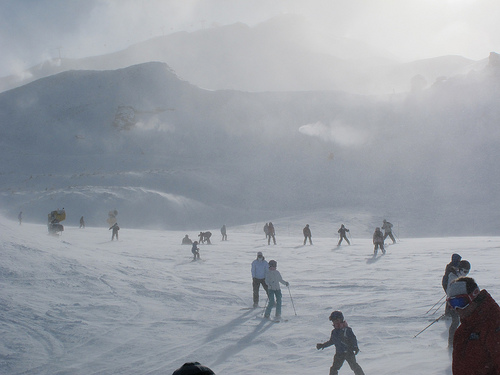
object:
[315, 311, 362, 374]
child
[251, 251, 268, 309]
person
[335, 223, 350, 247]
person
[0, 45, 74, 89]
hill side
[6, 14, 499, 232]
mountains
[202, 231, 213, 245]
person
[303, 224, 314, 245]
person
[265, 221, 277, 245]
person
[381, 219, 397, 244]
person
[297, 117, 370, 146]
snow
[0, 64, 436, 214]
hill side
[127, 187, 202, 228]
hill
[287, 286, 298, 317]
ski pole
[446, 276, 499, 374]
man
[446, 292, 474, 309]
goggles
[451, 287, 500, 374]
black coat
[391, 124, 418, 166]
ground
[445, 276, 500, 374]
people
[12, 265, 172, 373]
path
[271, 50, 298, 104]
snow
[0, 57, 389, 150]
hill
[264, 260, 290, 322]
people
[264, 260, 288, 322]
person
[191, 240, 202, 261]
children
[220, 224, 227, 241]
person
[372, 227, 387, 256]
people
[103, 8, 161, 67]
snow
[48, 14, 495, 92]
hill side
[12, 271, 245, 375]
tracks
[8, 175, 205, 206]
snow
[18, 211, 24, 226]
person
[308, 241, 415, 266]
snow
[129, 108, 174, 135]
snow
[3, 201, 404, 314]
group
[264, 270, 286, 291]
coat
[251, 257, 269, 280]
coat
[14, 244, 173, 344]
snow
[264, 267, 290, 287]
coat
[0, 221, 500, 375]
hill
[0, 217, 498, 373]
area